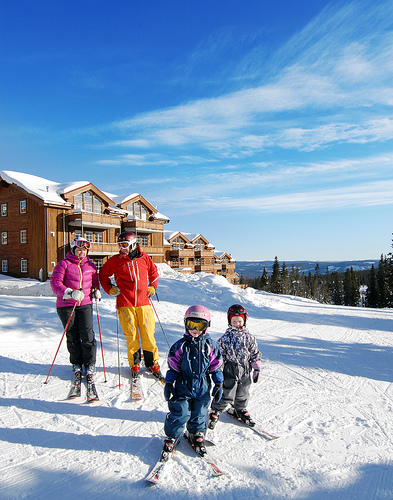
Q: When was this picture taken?
A: Daytime.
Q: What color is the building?
A: Brown.